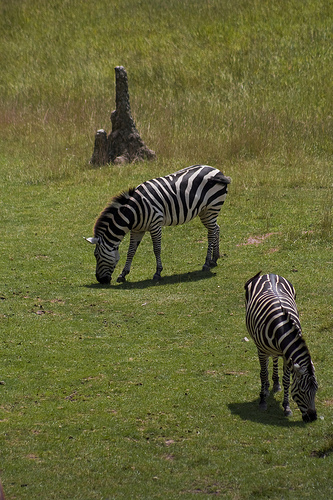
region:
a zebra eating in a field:
[83, 162, 231, 288]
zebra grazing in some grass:
[239, 266, 321, 429]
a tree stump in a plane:
[87, 62, 156, 173]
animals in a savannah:
[80, 60, 323, 433]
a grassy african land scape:
[44, 41, 320, 450]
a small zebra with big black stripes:
[80, 162, 234, 291]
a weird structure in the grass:
[87, 64, 157, 169]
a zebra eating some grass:
[82, 163, 230, 287]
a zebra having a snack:
[242, 269, 320, 425]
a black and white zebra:
[84, 164, 232, 287]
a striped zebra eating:
[84, 162, 233, 286]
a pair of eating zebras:
[81, 161, 320, 425]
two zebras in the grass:
[79, 162, 321, 425]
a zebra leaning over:
[78, 161, 231, 283]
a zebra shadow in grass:
[224, 384, 310, 429]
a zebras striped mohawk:
[91, 185, 141, 238]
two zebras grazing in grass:
[81, 158, 320, 426]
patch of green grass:
[63, 340, 93, 371]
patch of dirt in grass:
[161, 434, 177, 448]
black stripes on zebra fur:
[132, 185, 208, 211]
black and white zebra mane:
[90, 181, 136, 239]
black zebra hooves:
[252, 378, 295, 421]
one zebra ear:
[80, 230, 99, 248]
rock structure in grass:
[82, 57, 158, 172]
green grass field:
[1, 0, 332, 497]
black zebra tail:
[206, 169, 234, 188]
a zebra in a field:
[84, 161, 232, 287]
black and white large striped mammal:
[76, 165, 241, 287]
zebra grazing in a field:
[241, 269, 322, 432]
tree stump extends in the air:
[78, 61, 159, 169]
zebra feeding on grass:
[76, 164, 234, 287]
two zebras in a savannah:
[74, 165, 321, 430]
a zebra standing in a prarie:
[82, 159, 232, 289]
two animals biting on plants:
[79, 159, 321, 429]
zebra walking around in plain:
[235, 271, 321, 431]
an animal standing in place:
[71, 162, 247, 289]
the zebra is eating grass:
[82, 221, 136, 294]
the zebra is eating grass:
[74, 221, 125, 292]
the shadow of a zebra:
[146, 263, 218, 304]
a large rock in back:
[74, 41, 164, 174]